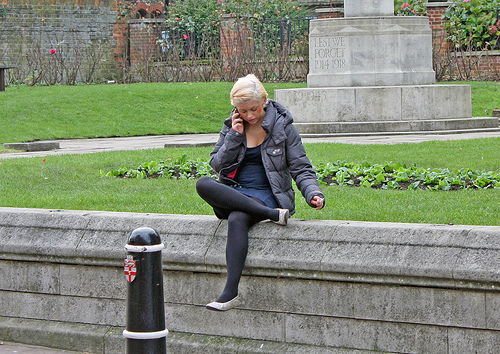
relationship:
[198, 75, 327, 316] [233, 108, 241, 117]
woman talking on phone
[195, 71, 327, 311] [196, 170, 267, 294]
woman wearing stockings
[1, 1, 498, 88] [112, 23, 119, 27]
wall made of brick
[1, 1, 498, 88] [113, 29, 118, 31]
wall made of brick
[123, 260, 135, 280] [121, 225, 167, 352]
red cross on cigarette post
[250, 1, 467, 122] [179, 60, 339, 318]
statue behind woman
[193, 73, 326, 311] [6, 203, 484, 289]
girl sitting on ledge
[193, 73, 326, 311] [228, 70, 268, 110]
girl with hair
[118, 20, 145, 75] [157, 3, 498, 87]
columns behind shrubs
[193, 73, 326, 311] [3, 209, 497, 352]
girl sitting on wall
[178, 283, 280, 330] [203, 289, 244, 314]
flats on feet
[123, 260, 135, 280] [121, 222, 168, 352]
red cross on pole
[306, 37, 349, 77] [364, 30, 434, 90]
letters in concrete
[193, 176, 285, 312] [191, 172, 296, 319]
stockings on legs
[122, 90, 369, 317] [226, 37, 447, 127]
girl sitting on wall